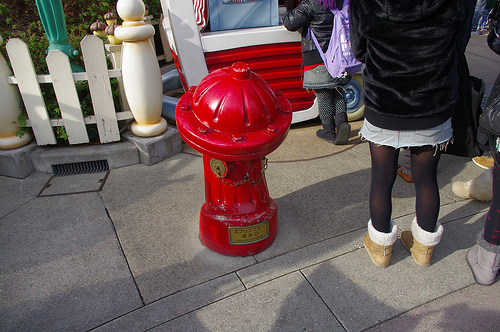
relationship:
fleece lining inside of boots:
[366, 216, 444, 246] [361, 216, 443, 267]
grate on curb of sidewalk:
[50, 158, 109, 177] [1, 31, 499, 331]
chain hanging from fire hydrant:
[211, 159, 268, 186] [174, 60, 295, 257]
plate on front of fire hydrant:
[226, 217, 270, 244] [174, 60, 295, 257]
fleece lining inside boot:
[474, 228, 498, 255] [466, 226, 499, 287]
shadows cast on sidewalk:
[2, 151, 498, 331] [1, 31, 499, 331]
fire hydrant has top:
[174, 60, 295, 257] [174, 60, 293, 163]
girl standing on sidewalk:
[280, 2, 361, 145] [1, 31, 499, 331]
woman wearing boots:
[346, 0, 476, 268] [361, 216, 443, 267]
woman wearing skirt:
[346, 0, 476, 268] [357, 117, 454, 154]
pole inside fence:
[34, 0, 86, 84] [0, 1, 167, 152]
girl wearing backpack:
[280, 2, 361, 145] [309, 0, 362, 78]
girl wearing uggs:
[280, 2, 361, 145] [314, 111, 350, 146]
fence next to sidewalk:
[0, 1, 167, 152] [1, 31, 499, 331]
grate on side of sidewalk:
[50, 158, 109, 177] [1, 31, 499, 331]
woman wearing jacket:
[346, 0, 476, 268] [346, 2, 475, 118]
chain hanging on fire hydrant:
[211, 159, 268, 186] [174, 60, 295, 257]